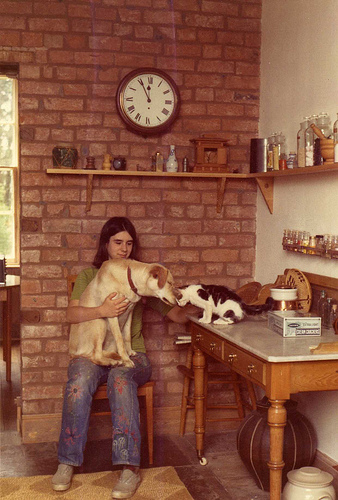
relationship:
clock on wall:
[106, 58, 188, 142] [0, 1, 260, 452]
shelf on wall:
[40, 152, 261, 227] [0, 1, 260, 452]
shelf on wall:
[250, 148, 337, 222] [250, 3, 336, 463]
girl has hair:
[50, 214, 158, 500] [86, 212, 141, 278]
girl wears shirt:
[50, 214, 158, 500] [58, 262, 179, 370]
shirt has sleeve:
[58, 262, 179, 370] [142, 295, 178, 321]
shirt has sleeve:
[58, 262, 179, 370] [65, 272, 93, 309]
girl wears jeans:
[50, 214, 158, 500] [54, 347, 155, 475]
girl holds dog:
[50, 214, 158, 500] [64, 251, 179, 375]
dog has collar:
[64, 251, 179, 375] [123, 258, 149, 305]